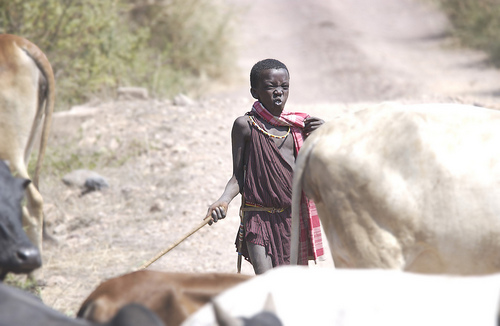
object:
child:
[205, 58, 325, 277]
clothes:
[232, 116, 316, 269]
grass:
[0, 1, 237, 109]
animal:
[289, 101, 500, 279]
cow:
[0, 160, 102, 325]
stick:
[133, 217, 212, 273]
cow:
[0, 33, 62, 285]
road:
[33, 0, 500, 312]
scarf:
[253, 102, 329, 267]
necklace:
[247, 112, 295, 140]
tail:
[284, 132, 315, 264]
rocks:
[145, 201, 167, 213]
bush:
[0, 1, 247, 93]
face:
[0, 162, 44, 273]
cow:
[109, 292, 285, 325]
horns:
[211, 295, 245, 325]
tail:
[20, 41, 59, 189]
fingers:
[211, 209, 219, 223]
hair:
[249, 58, 292, 89]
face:
[258, 69, 289, 109]